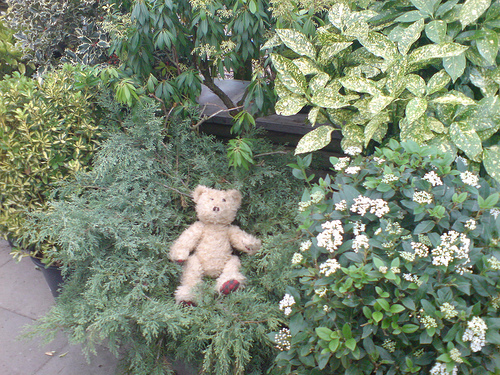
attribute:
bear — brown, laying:
[165, 169, 263, 315]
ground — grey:
[5, 255, 178, 374]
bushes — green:
[2, 1, 285, 359]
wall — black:
[170, 72, 355, 161]